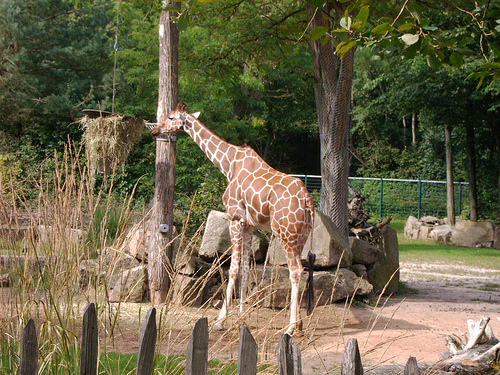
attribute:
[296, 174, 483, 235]
fence — green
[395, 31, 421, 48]
leaf — green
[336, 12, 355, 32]
leaf — green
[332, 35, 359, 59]
leaf — green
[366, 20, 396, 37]
leaf — green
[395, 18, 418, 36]
leaf — green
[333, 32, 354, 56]
leaf — green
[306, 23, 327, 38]
leaf — green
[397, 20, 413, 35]
leaf — green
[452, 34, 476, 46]
leaf — green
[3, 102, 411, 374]
grass — brow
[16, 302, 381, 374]
fence — brown staked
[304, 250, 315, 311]
tail — black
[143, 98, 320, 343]
giraffe — tall